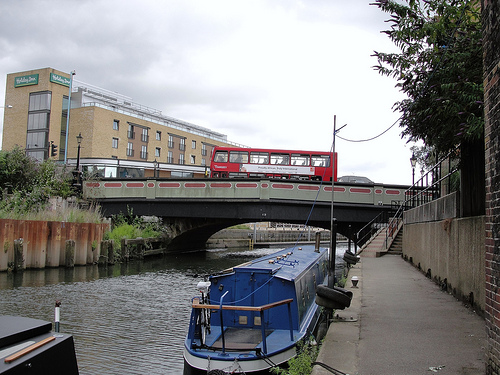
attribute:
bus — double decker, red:
[183, 112, 388, 194]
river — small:
[10, 218, 327, 356]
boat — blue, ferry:
[154, 232, 355, 370]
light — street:
[303, 95, 367, 151]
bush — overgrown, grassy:
[16, 164, 130, 191]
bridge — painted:
[140, 160, 443, 225]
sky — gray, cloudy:
[133, 45, 307, 105]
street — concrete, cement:
[304, 232, 498, 359]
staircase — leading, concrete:
[337, 141, 443, 279]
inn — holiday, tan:
[1, 55, 290, 205]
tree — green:
[395, 38, 499, 176]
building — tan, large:
[22, 45, 233, 179]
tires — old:
[308, 278, 367, 320]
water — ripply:
[97, 252, 199, 305]